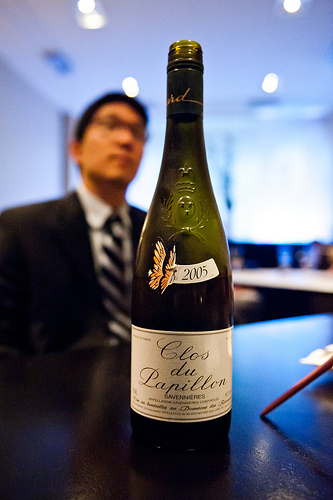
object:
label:
[148, 241, 219, 291]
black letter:
[137, 337, 230, 394]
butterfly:
[146, 235, 177, 296]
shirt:
[75, 179, 136, 345]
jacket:
[0, 187, 145, 354]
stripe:
[97, 240, 128, 283]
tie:
[99, 213, 131, 344]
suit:
[0, 187, 155, 357]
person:
[0, 90, 149, 350]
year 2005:
[181, 263, 207, 280]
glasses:
[92, 115, 153, 145]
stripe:
[101, 223, 122, 247]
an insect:
[139, 243, 181, 292]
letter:
[156, 339, 181, 358]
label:
[129, 323, 231, 424]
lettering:
[133, 334, 227, 413]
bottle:
[131, 39, 230, 454]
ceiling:
[224, 18, 295, 89]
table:
[231, 267, 331, 294]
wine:
[117, 37, 235, 444]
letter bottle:
[185, 362, 196, 380]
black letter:
[177, 344, 193, 360]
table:
[2, 300, 330, 498]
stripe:
[104, 308, 133, 334]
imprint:
[155, 177, 217, 231]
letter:
[136, 366, 159, 387]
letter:
[155, 379, 164, 390]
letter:
[163, 381, 178, 394]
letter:
[180, 379, 189, 389]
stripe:
[100, 227, 131, 340]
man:
[1, 86, 166, 364]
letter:
[200, 370, 216, 393]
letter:
[169, 357, 194, 380]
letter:
[188, 346, 202, 364]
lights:
[261, 73, 279, 94]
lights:
[281, 0, 302, 14]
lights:
[121, 76, 138, 97]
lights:
[75, 0, 104, 28]